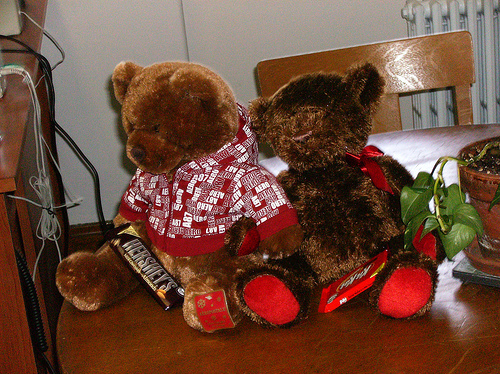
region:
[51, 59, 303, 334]
a cute little teddy bear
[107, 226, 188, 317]
a Hershey's chocolate bar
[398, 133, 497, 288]
a potted plant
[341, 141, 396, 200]
a ribbon tied onto a teddy bear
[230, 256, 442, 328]
the paws of a teddy bear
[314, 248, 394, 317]
a Kit Kat candy bar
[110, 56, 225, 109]
the ears of a teddy bear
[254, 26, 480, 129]
the back of a wooden chair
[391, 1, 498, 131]
a radiator type heater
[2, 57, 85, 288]
phone cords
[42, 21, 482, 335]
Two brown teddy bears.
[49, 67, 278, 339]
The bear has a red jacket on.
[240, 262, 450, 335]
The bottoms of this bear's feet are red.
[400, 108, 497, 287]
A plant in a ceramic pot.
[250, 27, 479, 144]
A wooden chair.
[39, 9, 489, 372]
The bears are on a table.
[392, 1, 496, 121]
A radiator.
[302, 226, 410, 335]
A Kit Kat bar .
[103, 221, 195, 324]
A Hershey's chocolate bar.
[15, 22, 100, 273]
A bunch of cables.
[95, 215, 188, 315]
Hershey's chocolate bar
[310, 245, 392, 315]
KitKat chocolate bar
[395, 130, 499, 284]
Small house plant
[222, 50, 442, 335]
Brown teddy bear with red feet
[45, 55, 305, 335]
Brown teddy bear wearing a jacket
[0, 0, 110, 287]
Computer cables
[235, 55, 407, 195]
Red ribbon tied to a teddy bear's neck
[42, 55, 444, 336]
Two teddy bears holding hands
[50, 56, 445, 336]
Two stuffed animals of different brown color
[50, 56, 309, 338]
Teddy bear with tag attached to foot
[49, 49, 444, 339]
TWO TEDDY BEARS ON A TABLE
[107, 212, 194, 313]
A HERSHEY BAR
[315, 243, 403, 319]
A KIT KAT CHOCOLATE BAR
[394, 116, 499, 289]
A FLOWER POT ON THE TABLE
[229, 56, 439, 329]
A BROWN TEDDY BEAR WITH RED FEET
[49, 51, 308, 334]
A RED SHIRT ON A TEDDY BEAR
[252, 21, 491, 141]
A WOODEN CHAIR AT THE TABLE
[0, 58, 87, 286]
TELEPHONE CORDS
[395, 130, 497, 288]
A GREEN PLANT IN A FLOWER POT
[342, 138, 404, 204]
A RED RIBBON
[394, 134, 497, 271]
shiny leafed green potted plant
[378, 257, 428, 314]
red oval fabric pads of teddy bear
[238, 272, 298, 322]
red oval fabric pads of teddy bear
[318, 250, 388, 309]
kit kat chocolate bar in wrapper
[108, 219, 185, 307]
hersey's chocolate bar in wrapper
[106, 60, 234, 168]
plush brown furry teddy bear head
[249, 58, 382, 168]
plush brown furry teddy bear head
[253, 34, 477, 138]
back of a wooden chair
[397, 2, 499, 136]
white painted metal radiator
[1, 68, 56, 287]
long white electrical cord